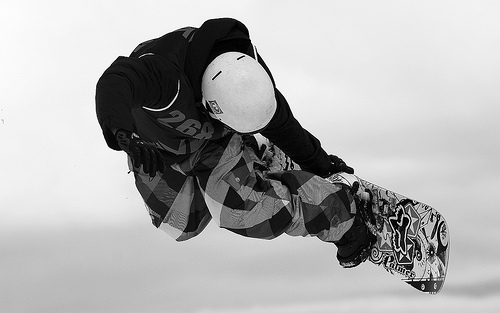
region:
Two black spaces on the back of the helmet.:
[208, 51, 248, 76]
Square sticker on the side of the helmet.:
[206, 97, 226, 119]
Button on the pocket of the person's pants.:
[235, 170, 241, 185]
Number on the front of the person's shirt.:
[160, 101, 215, 142]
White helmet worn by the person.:
[196, 46, 278, 136]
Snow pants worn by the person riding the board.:
[134, 157, 370, 259]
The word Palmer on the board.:
[383, 249, 422, 282]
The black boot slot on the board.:
[317, 203, 381, 273]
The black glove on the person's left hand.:
[104, 129, 180, 183]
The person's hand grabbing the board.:
[301, 126, 356, 190]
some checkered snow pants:
[103, 124, 363, 255]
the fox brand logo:
[385, 202, 417, 262]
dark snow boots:
[333, 184, 376, 279]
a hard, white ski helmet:
[194, 40, 287, 145]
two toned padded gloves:
[106, 121, 176, 182]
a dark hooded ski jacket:
[86, 7, 383, 197]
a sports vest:
[107, 22, 239, 162]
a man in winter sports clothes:
[65, 9, 425, 279]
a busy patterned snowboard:
[240, 128, 468, 303]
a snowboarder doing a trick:
[73, 5, 485, 294]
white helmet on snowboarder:
[201, 46, 281, 138]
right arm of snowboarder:
[92, 53, 188, 181]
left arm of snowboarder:
[243, 24, 354, 174]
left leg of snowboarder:
[206, 143, 376, 269]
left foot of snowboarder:
[336, 183, 383, 270]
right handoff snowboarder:
[107, 124, 171, 181]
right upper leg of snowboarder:
[125, 156, 217, 242]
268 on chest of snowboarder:
[159, 103, 214, 145]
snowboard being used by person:
[352, 173, 457, 301]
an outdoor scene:
[3, 2, 490, 297]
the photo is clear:
[1, 3, 496, 309]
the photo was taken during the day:
[4, 3, 499, 308]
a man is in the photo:
[74, 4, 464, 301]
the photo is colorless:
[1, 2, 493, 312]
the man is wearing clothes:
[67, 8, 454, 275]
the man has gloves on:
[102, 112, 175, 188]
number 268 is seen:
[158, 102, 237, 172]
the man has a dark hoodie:
[77, 7, 441, 231]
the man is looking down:
[163, 45, 353, 239]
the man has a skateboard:
[306, 153, 481, 304]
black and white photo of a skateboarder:
[16, 1, 470, 293]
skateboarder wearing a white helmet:
[77, 12, 451, 310]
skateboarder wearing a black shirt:
[79, 16, 463, 293]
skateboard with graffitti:
[198, 138, 490, 300]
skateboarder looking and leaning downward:
[83, 9, 463, 289]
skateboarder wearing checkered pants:
[123, 132, 405, 272]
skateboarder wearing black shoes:
[264, 144, 426, 302]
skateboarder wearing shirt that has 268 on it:
[78, 20, 326, 190]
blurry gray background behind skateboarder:
[17, 9, 498, 295]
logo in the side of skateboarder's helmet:
[187, 53, 289, 151]